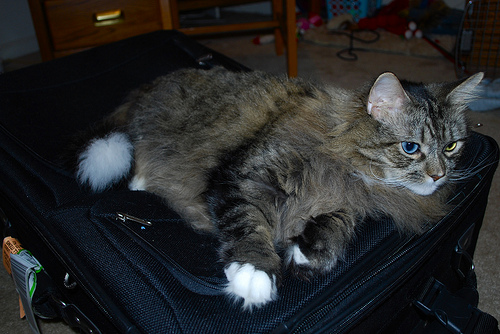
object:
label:
[2, 235, 28, 275]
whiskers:
[449, 150, 496, 182]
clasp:
[116, 206, 152, 227]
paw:
[223, 250, 282, 312]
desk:
[161, 0, 300, 76]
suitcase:
[0, 29, 500, 333]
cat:
[77, 68, 494, 314]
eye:
[397, 134, 422, 157]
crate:
[323, 0, 369, 21]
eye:
[442, 136, 463, 155]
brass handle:
[93, 9, 121, 23]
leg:
[285, 0, 298, 80]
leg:
[272, 0, 287, 58]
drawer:
[40, 0, 163, 51]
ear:
[364, 71, 411, 120]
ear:
[440, 69, 486, 106]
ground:
[0, 27, 500, 331]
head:
[335, 70, 486, 200]